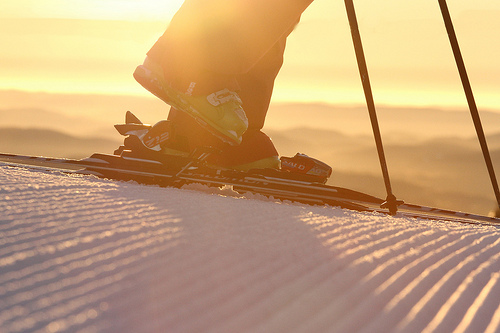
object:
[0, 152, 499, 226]
ski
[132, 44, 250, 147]
ski boot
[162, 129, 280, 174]
ski boot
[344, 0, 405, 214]
ski poles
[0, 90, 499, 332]
mountain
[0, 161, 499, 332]
snow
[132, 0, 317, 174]
skier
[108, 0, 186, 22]
glare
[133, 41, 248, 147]
foot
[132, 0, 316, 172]
person